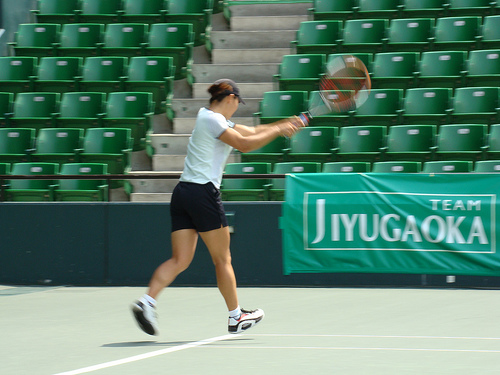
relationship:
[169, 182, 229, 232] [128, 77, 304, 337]
pants on player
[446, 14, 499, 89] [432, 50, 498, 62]
seats have white lettering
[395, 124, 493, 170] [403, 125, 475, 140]
seats have white lettering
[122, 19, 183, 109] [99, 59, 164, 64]
seats have white lettering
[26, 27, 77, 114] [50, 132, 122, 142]
seats have white lettering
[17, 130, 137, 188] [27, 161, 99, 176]
seats have white lettering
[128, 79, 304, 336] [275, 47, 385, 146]
player has racket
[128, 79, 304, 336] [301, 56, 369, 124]
player has racket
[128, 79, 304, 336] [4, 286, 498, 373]
player in tennis court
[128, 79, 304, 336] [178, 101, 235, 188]
player has shirt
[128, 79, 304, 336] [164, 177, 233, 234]
player has shorts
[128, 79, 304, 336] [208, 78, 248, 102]
player has cap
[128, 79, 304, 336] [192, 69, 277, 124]
player wearing a hat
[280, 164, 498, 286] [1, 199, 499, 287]
sign on wall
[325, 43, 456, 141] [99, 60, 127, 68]
seats have tag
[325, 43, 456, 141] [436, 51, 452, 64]
seats have tag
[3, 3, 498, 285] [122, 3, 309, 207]
stadium has stairs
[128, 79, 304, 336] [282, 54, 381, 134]
player holding racket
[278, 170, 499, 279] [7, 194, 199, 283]
banner on wall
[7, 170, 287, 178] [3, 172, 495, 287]
railing on wall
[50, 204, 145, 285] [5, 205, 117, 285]
padding on wall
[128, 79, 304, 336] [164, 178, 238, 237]
player wearing shorts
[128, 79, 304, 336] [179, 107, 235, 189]
player wearing blouse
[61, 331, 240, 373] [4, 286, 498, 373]
lines on tennis court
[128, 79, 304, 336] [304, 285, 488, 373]
player running court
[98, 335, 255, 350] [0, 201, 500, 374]
shadow on court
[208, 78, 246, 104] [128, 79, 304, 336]
cap on player